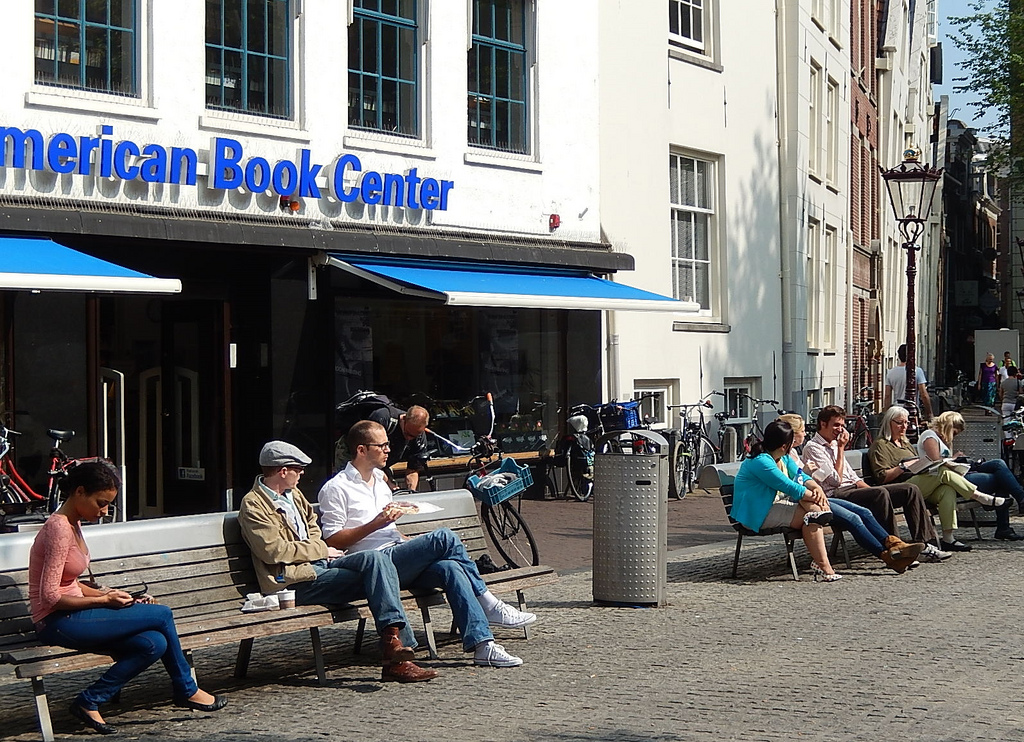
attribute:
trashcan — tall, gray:
[583, 443, 676, 610]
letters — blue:
[75, 133, 97, 172]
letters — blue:
[94, 119, 120, 178]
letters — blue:
[110, 135, 136, 177]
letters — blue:
[136, 145, 158, 174]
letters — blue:
[172, 141, 203, 180]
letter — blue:
[209, 130, 244, 197]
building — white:
[4, 5, 623, 610]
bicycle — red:
[4, 424, 126, 546]